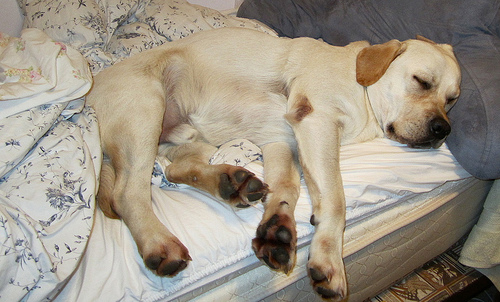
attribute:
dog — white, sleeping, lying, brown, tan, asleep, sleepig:
[72, 36, 496, 268]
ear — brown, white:
[357, 43, 405, 82]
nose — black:
[430, 119, 451, 136]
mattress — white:
[15, 29, 430, 301]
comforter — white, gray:
[12, 4, 228, 36]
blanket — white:
[1, 25, 83, 105]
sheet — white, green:
[9, 112, 100, 266]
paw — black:
[255, 216, 299, 267]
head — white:
[364, 36, 463, 136]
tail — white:
[92, 162, 118, 210]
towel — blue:
[462, 179, 498, 274]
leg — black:
[181, 155, 261, 203]